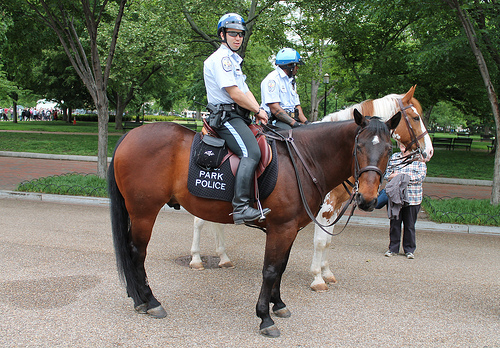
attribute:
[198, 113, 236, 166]
bag — black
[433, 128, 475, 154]
bench — wooden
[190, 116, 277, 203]
saddle — black